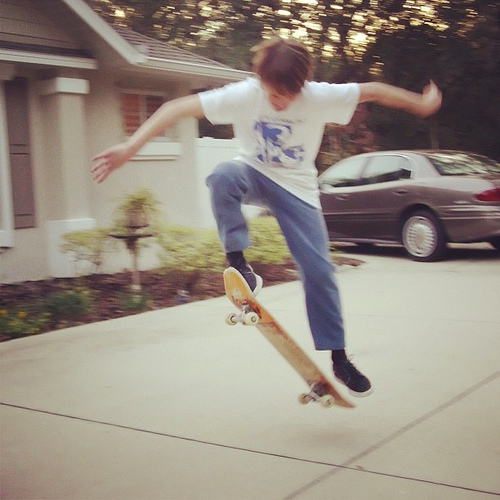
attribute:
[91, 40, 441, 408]
skateboarder —  skater, performing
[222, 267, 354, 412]
skateboard — orange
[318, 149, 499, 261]
grey car — four,  door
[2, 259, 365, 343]
front garden — growing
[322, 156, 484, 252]
vehicle — grey